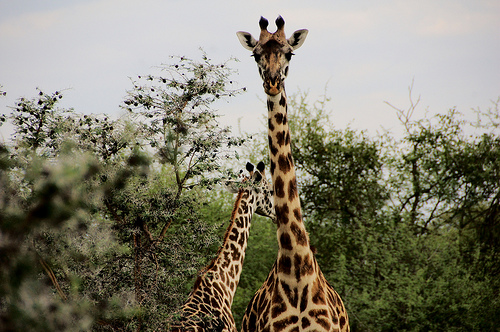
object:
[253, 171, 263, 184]
ear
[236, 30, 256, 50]
ear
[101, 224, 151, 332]
thorns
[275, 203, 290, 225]
spot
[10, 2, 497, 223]
sky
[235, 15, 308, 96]
head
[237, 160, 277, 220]
head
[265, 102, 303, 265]
neck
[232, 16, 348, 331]
giraffe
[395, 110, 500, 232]
trees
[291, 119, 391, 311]
tree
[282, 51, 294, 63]
eye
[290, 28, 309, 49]
giraffe ear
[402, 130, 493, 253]
bush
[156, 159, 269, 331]
giraffe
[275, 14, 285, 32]
horns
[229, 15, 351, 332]
giraffe's head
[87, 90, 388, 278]
camera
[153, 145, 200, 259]
left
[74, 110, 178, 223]
tip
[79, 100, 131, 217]
up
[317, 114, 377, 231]
right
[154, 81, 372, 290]
number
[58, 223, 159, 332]
color